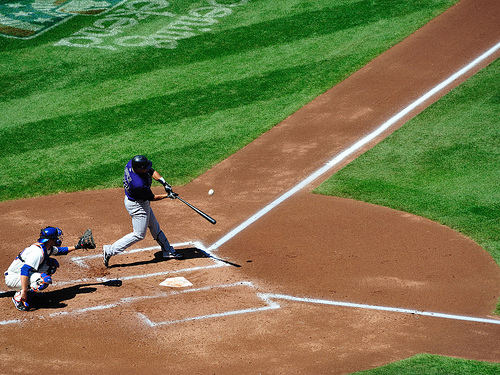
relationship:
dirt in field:
[0, 0, 499, 372] [2, 0, 484, 370]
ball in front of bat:
[206, 186, 215, 198] [153, 175, 217, 224]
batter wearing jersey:
[100, 153, 221, 273] [120, 162, 159, 206]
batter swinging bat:
[100, 153, 221, 273] [157, 177, 219, 227]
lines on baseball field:
[2, 47, 499, 367] [3, 0, 498, 370]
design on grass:
[0, 0, 244, 56] [3, 0, 462, 197]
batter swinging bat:
[102, 153, 184, 269] [159, 174, 219, 239]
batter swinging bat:
[102, 153, 184, 269] [173, 193, 217, 243]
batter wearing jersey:
[102, 153, 184, 269] [123, 159, 154, 201]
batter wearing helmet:
[102, 153, 184, 269] [129, 153, 157, 172]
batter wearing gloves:
[102, 153, 184, 269] [162, 181, 176, 202]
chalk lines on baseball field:
[88, 231, 307, 335] [3, 0, 498, 370]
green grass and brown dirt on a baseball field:
[149, 88, 467, 188] [27, 101, 409, 293]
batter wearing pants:
[102, 153, 184, 269] [116, 197, 156, 246]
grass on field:
[83, 55, 217, 152] [94, 118, 395, 370]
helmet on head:
[35, 222, 60, 245] [36, 223, 65, 253]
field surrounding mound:
[2, 0, 484, 370] [6, 196, 448, 373]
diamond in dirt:
[155, 273, 194, 292] [22, 196, 349, 373]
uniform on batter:
[112, 196, 168, 250] [102, 153, 184, 269]